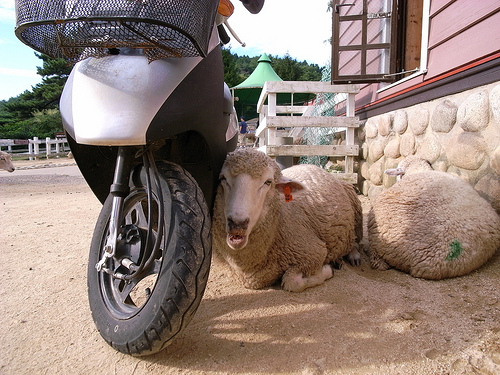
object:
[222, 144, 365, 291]
lamb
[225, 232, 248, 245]
mouth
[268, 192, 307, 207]
tag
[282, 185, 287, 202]
numbers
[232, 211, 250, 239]
nose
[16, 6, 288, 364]
motorcycle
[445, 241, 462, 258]
stain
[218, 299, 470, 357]
ground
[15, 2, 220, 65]
basket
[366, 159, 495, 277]
sheep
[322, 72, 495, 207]
wall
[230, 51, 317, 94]
umbrella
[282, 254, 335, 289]
leg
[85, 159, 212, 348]
tire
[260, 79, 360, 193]
fence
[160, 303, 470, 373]
shadow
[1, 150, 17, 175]
sheep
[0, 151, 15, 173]
head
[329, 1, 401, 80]
window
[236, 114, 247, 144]
people